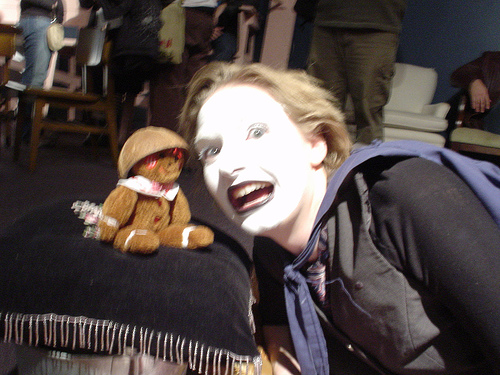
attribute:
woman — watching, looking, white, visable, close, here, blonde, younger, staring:
[198, 65, 360, 262]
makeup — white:
[237, 147, 302, 182]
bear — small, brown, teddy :
[99, 124, 198, 250]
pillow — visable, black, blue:
[19, 169, 109, 330]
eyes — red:
[147, 144, 184, 170]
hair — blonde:
[171, 49, 360, 253]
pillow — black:
[5, 148, 270, 372]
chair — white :
[376, 57, 457, 161]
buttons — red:
[151, 198, 166, 234]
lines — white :
[102, 205, 207, 252]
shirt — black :
[283, 153, 496, 370]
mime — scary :
[182, 60, 498, 372]